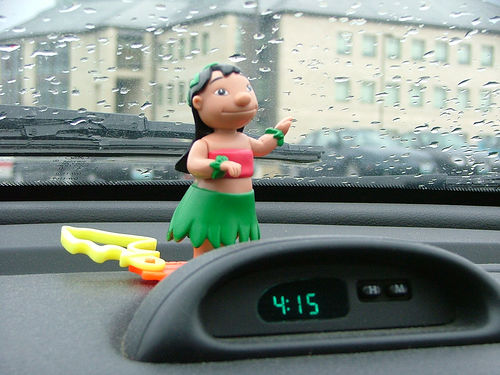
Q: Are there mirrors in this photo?
A: No, there are no mirrors.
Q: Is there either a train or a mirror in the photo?
A: No, there are no mirrors or trains.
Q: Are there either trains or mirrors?
A: No, there are no mirrors or trains.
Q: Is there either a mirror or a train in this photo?
A: No, there are no mirrors or trains.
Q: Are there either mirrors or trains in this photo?
A: No, there are no mirrors or trains.